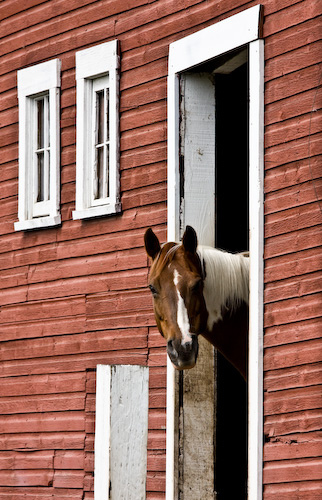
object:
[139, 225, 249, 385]
horse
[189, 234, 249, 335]
fur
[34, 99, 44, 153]
window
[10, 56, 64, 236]
frame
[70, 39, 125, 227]
frame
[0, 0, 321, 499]
wall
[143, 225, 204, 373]
head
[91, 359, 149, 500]
pole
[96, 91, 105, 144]
window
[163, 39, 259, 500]
opening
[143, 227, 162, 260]
ear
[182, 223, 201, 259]
ear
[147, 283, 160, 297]
eye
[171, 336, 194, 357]
nose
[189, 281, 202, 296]
eye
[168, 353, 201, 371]
mouth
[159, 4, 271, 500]
trim